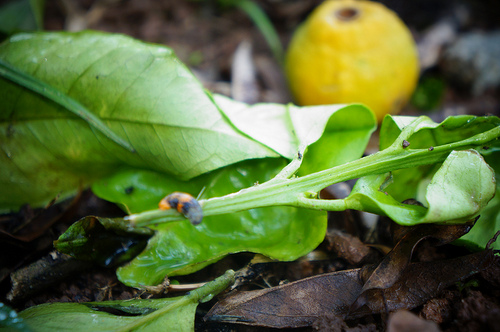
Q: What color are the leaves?
A: Green.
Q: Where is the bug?
A: On the leaves.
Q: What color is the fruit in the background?
A: Yellow.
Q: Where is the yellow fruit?
A: Behind the leaves.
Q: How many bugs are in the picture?
A: One.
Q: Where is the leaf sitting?
A: On the ground.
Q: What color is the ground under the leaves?
A: Brown.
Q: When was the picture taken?
A: Daytime.